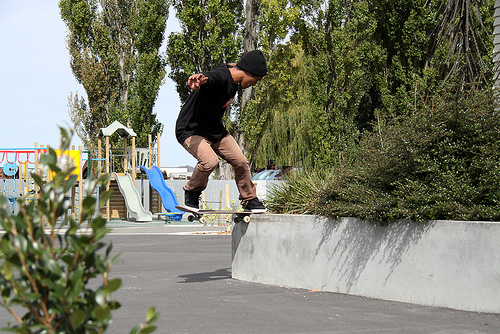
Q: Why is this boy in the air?
A: Skateboarding tricks.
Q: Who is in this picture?
A: A boy skateboarding.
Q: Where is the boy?
A: In the air in his skateboard.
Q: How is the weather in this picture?
A: Clear and sunny.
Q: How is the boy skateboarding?
A: Using the wall.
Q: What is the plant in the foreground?
A: A shrub.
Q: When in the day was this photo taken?
A: In the afternoon.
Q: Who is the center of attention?
A: The boy on the skateboard.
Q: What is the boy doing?
A: Skateboarding.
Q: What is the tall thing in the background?
A: Tree.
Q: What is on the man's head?
A: Hat.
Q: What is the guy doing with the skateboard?
A: A trick.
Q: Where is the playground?
A: Behind the guy.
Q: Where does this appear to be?
A: A park.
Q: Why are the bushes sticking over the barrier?
A: They need trimmed.